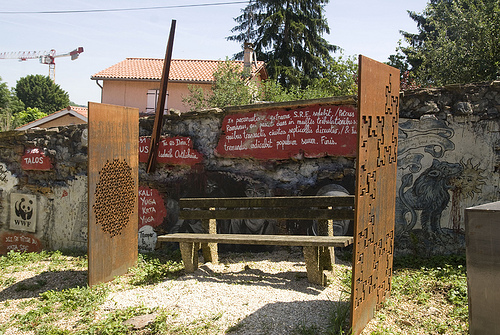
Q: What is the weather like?
A: Sunny with clouds.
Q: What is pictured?
A: Bench.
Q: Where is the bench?
A: Between two walls.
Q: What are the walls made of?
A: Metal.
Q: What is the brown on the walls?
A: Rust.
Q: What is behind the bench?
A: Wall.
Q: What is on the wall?
A: Mural.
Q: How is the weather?
A: Sunny.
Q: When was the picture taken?
A: During day hours.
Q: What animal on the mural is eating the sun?
A: Lion.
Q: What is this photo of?
A: A ranch.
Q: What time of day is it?
A: It is daytime.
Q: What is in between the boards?
A: A bench.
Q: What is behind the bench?
A: A wall.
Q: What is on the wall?
A: A sign.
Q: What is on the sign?
A: White lettering.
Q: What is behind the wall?
A: A house.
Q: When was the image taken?
A: During the day.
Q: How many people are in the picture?
A: No people in the image.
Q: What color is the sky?
A: Blue.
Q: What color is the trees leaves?
A: Green.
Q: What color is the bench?
A: Brown.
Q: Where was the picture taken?
A: On the street.